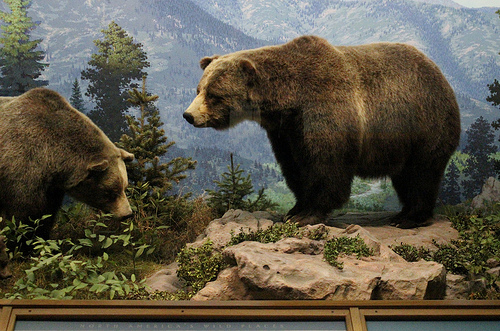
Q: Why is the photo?
A: Empty.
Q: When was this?
A: Daytime.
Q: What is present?
A: Bears.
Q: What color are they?
A: Brown.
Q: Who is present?
A: Nobody.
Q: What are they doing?
A: Playing.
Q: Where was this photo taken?
A: A museum.